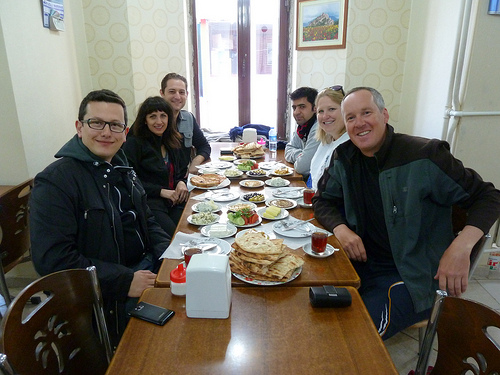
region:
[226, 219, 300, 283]
A plate full of chapati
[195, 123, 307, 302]
A table full of food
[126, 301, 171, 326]
A black mobile phone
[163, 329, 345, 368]
A brown wooden table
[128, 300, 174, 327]
a black cell phone on the table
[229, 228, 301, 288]
a paper plate of pita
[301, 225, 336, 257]
a glass and saucer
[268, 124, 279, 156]
a plastic bottle of water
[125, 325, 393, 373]
a wooden dining table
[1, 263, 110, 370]
a wooden dining chair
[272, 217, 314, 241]
a ceramic dinner plate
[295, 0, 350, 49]
a framed picture on the wall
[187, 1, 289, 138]
a wood frame double french door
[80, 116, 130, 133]
black framed eye glasses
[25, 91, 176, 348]
person sitting next to person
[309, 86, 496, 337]
person sitting next to person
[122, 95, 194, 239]
person sitting next to person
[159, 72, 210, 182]
person sitting next to personperson sitting next to person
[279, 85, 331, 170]
person sitting next to person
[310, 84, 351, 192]
person sitting next to person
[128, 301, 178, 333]
black cell phone on wooden table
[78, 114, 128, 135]
glasses with black rim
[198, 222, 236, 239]
round plate is white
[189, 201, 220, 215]
round plate is white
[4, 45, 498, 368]
people sitting a table for a meal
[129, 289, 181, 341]
phone on a table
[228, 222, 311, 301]
pita bread on a plate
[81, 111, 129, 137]
glasses on a man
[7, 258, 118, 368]
wooden chair at a table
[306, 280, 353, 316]
wallet on a table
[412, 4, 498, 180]
refrigerator in a kitchen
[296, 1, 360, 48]
framed picture on the wall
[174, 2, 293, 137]
doors in a room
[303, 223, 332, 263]
beverage in a glass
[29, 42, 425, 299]
group of people sitting at table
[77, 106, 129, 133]
black glasses on face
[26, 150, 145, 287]
large black jacket on person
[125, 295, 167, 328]
black cell phone on table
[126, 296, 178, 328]
cell phone upside down on table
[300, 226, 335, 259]
small white plate on table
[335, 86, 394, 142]
head of man on table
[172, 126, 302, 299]
white plates on table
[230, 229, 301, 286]
large stack of pita bread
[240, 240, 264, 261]
white and black pita bread